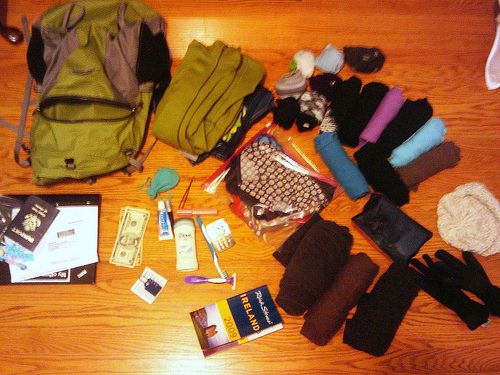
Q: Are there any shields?
A: No, there are no shields.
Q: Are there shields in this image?
A: No, there are no shields.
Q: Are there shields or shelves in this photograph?
A: No, there are no shields or shelves.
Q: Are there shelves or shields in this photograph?
A: No, there are no shields or shelves.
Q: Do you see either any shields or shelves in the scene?
A: No, there are no shields or shelves.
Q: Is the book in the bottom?
A: Yes, the book is in the bottom of the image.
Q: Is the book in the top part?
A: No, the book is in the bottom of the image.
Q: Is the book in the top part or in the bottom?
A: The book is in the bottom of the image.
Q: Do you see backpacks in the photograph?
A: Yes, there is a backpack.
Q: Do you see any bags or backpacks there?
A: Yes, there is a backpack.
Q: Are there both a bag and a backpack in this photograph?
A: Yes, there are both a backpack and a bag.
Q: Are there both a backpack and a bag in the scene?
A: Yes, there are both a backpack and a bag.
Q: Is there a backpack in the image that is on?
A: Yes, there is a backpack that is on.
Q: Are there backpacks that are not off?
A: Yes, there is a backpack that is on.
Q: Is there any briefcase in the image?
A: No, there are no briefcases.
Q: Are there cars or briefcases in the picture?
A: No, there are no briefcases or cars.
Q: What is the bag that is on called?
A: The bag is a backpack.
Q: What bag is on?
A: The bag is a backpack.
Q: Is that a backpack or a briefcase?
A: That is a backpack.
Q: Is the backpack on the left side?
A: Yes, the backpack is on the left of the image.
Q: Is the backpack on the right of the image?
A: No, the backpack is on the left of the image.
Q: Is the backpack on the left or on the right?
A: The backpack is on the left of the image.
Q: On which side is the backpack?
A: The backpack is on the left of the image.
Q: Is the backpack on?
A: Yes, the backpack is on.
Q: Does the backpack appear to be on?
A: Yes, the backpack is on.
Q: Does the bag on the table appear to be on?
A: Yes, the backpack is on.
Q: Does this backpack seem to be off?
A: No, the backpack is on.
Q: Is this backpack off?
A: No, the backpack is on.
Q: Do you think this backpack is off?
A: No, the backpack is on.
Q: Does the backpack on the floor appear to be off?
A: No, the backpack is on.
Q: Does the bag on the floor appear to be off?
A: No, the backpack is on.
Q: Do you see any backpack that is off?
A: No, there is a backpack but it is on.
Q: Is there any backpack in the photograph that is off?
A: No, there is a backpack but it is on.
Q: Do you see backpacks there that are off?
A: No, there is a backpack but it is on.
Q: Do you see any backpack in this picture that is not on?
A: No, there is a backpack but it is on.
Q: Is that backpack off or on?
A: The backpack is on.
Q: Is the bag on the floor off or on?
A: The backpack is on.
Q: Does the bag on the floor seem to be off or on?
A: The backpack is on.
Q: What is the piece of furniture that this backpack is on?
A: The piece of furniture is a table.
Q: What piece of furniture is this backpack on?
A: The backpack is on the table.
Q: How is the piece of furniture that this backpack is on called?
A: The piece of furniture is a table.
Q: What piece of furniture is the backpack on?
A: The backpack is on the table.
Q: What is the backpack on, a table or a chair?
A: The backpack is on a table.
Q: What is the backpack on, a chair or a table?
A: The backpack is on a table.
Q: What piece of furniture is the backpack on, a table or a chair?
A: The backpack is on a table.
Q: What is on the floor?
A: The backpack is on the floor.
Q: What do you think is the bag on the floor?
A: The bag is a backpack.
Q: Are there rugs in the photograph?
A: No, there are no rugs.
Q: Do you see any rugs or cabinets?
A: No, there are no rugs or cabinets.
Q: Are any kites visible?
A: No, there are no kites.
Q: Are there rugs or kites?
A: No, there are no kites or rugs.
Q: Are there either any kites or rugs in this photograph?
A: No, there are no kites or rugs.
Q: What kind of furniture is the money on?
A: The money is on the table.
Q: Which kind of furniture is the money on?
A: The money is on the table.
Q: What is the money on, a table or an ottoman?
A: The money is on a table.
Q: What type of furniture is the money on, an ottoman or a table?
A: The money is on a table.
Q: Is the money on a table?
A: Yes, the money is on a table.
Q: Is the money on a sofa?
A: No, the money is on a table.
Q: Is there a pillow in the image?
A: No, there are no pillows.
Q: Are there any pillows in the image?
A: No, there are no pillows.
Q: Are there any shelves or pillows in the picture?
A: No, there are no pillows or shelves.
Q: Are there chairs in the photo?
A: No, there are no chairs.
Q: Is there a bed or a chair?
A: No, there are no chairs or beds.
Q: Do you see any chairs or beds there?
A: No, there are no chairs or beds.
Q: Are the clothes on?
A: Yes, the clothes are on.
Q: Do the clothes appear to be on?
A: Yes, the clothes are on.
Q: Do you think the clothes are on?
A: Yes, the clothes are on.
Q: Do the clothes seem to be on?
A: Yes, the clothes are on.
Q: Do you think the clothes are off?
A: No, the clothes are on.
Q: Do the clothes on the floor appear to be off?
A: No, the clothes are on.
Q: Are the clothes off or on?
A: The clothes are on.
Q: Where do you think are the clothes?
A: The clothes are on the floor.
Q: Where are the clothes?
A: The clothes are on the floor.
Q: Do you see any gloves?
A: Yes, there are gloves.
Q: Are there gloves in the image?
A: Yes, there are gloves.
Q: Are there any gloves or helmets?
A: Yes, there are gloves.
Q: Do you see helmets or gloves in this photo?
A: Yes, there are gloves.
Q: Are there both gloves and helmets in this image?
A: No, there are gloves but no helmets.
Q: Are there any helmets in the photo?
A: No, there are no helmets.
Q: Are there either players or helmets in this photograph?
A: No, there are no helmets or players.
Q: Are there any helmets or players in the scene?
A: No, there are no helmets or players.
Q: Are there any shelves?
A: No, there are no shelves.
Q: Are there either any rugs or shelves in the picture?
A: No, there are no shelves or rugs.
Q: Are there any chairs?
A: No, there are no chairs.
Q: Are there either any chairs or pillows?
A: No, there are no chairs or pillows.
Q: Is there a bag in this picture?
A: Yes, there is a bag.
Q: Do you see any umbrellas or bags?
A: Yes, there is a bag.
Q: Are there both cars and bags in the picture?
A: No, there is a bag but no cars.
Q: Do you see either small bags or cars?
A: Yes, there is a small bag.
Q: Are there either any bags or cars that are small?
A: Yes, the bag is small.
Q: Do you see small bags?
A: Yes, there is a small bag.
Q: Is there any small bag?
A: Yes, there is a small bag.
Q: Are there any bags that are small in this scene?
A: Yes, there is a small bag.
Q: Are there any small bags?
A: Yes, there is a small bag.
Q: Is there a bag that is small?
A: Yes, there is a bag that is small.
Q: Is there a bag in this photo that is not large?
A: Yes, there is a small bag.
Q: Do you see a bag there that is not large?
A: Yes, there is a small bag.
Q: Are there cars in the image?
A: No, there are no cars.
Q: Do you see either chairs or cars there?
A: No, there are no cars or chairs.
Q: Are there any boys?
A: No, there are no boys.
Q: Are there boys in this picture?
A: No, there are no boys.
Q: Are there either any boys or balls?
A: No, there are no boys or balls.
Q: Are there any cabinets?
A: No, there are no cabinets.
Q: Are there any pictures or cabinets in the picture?
A: No, there are no cabinets or pictures.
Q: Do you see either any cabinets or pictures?
A: No, there are no cabinets or pictures.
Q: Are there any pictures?
A: No, there are no pictures.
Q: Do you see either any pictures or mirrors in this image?
A: No, there are no pictures or mirrors.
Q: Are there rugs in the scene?
A: No, there are no rugs.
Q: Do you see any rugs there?
A: No, there are no rugs.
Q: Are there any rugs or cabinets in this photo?
A: No, there are no rugs or cabinets.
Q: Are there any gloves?
A: Yes, there are gloves.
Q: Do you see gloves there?
A: Yes, there are gloves.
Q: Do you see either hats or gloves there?
A: Yes, there are gloves.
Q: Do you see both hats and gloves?
A: Yes, there are both gloves and a hat.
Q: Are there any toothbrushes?
A: Yes, there is a toothbrush.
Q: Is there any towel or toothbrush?
A: Yes, there is a toothbrush.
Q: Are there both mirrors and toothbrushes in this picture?
A: No, there is a toothbrush but no mirrors.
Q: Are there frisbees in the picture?
A: No, there are no frisbees.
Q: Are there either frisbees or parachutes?
A: No, there are no frisbees or parachutes.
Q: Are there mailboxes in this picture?
A: No, there are no mailboxes.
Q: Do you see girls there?
A: No, there are no girls.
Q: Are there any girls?
A: No, there are no girls.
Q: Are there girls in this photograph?
A: No, there are no girls.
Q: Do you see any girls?
A: No, there are no girls.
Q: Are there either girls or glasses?
A: No, there are no girls or glasses.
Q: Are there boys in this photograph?
A: No, there are no boys.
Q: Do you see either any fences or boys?
A: No, there are no boys or fences.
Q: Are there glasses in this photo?
A: No, there are no glasses.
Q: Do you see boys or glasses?
A: No, there are no glasses or boys.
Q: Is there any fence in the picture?
A: No, there are no fences.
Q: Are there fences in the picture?
A: No, there are no fences.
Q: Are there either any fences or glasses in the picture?
A: No, there are no fences or glasses.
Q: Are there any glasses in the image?
A: No, there are no glasses.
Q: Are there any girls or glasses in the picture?
A: No, there are no glasses or girls.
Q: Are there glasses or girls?
A: No, there are no glasses or girls.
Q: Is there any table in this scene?
A: Yes, there is a table.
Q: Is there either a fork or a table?
A: Yes, there is a table.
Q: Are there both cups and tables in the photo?
A: No, there is a table but no cups.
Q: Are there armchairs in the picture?
A: No, there are no armchairs.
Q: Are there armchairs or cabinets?
A: No, there are no armchairs or cabinets.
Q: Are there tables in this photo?
A: Yes, there is a table.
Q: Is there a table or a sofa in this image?
A: Yes, there is a table.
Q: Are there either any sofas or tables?
A: Yes, there is a table.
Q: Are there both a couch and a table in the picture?
A: No, there is a table but no couches.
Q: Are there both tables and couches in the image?
A: No, there is a table but no couches.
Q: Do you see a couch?
A: No, there are no couches.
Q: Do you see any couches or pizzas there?
A: No, there are no couches or pizzas.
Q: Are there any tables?
A: Yes, there is a table.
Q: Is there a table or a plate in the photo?
A: Yes, there is a table.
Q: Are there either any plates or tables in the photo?
A: Yes, there is a table.